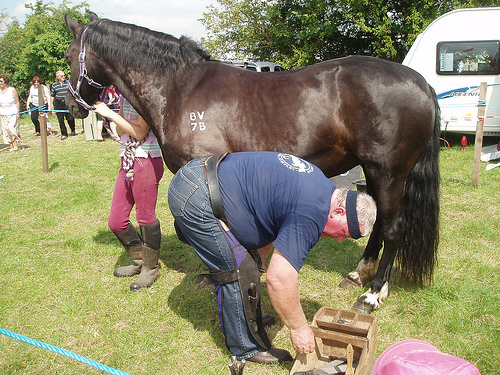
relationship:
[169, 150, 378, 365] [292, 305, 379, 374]
man over a box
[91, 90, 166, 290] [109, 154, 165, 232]
girl wearing pants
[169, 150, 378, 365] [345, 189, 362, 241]
man wearing a sweatband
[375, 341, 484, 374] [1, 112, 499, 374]
bag on top of grass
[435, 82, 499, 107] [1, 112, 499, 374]
rope above grass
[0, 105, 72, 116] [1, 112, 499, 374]
rope above grass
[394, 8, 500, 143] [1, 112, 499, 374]
trailer parked on top of grass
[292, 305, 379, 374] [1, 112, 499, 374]
box on top of grass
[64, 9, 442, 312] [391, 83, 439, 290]
horse has a tail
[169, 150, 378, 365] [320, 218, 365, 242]
man has a sunburn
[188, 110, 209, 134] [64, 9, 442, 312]
letters painted on horse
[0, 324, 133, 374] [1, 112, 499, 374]
hose on top of grass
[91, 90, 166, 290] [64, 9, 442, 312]
girl standing next to horse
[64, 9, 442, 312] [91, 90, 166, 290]
horse in front of girl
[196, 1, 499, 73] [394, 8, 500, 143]
tree behind trailer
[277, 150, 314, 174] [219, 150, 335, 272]
logo printed on t-shirt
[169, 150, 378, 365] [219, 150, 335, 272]
man wearing a t-shirt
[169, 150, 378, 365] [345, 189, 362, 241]
man wearing sweatband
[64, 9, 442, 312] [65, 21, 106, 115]
horse wearing a rein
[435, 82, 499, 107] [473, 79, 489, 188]
rope tied to post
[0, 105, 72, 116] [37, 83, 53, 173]
rope tied to post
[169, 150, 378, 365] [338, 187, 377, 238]
man has hair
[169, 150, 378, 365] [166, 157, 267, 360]
man wearing jeans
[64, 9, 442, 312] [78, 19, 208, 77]
horse has hair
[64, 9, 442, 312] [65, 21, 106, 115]
horse wearing rein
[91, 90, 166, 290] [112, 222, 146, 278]
girl wearing boot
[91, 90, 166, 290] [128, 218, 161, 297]
girl wearing boot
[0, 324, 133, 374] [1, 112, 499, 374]
hose on grass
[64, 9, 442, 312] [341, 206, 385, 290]
horse has right foot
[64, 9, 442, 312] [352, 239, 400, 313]
horse has left foot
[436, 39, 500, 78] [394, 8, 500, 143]
window on a trailer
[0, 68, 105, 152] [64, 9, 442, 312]
people watching horse